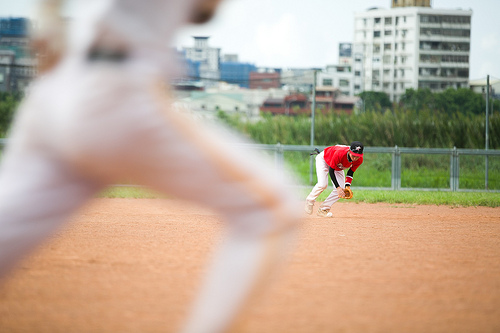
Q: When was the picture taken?
A: Daytime.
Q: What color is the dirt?
A: Brown.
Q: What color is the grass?
A: Green.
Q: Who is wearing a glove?
A: The man in the red shirt.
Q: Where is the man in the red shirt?
A: On the dirt.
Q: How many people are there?
A: Two.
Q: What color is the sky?
A: Gray.